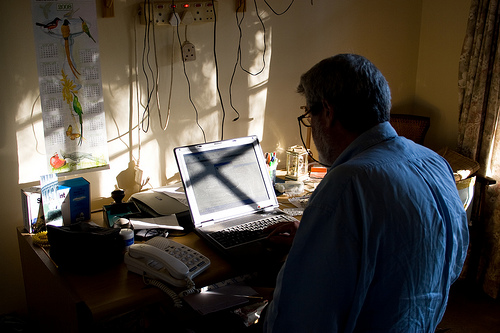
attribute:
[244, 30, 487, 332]
man — collared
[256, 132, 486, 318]
collared shirt — blue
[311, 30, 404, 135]
hair — dark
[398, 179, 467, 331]
wrinkles — black 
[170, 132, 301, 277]
laptop — open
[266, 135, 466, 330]
shirt — blue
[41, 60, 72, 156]
calendar — white 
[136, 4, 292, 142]
cables — black 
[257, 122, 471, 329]
shirt — blue, collared, black 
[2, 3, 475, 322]
wall — tall